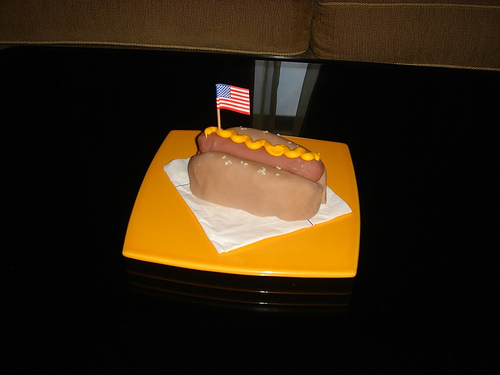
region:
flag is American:
[204, 80, 253, 132]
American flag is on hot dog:
[183, 83, 326, 219]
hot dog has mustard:
[196, 123, 327, 181]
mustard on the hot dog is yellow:
[198, 121, 326, 174]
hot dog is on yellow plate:
[121, 126, 361, 279]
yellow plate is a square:
[123, 127, 358, 279]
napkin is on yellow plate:
[124, 115, 359, 278]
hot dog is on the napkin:
[162, 120, 352, 249]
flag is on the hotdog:
[196, 83, 327, 181]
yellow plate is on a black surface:
[0, 59, 494, 368]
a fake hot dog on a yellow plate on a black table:
[153, 103, 369, 250]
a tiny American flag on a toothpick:
[214, 76, 254, 136]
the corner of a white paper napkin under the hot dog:
[184, 205, 265, 268]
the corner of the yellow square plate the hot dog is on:
[103, 205, 201, 289]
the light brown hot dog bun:
[194, 171, 311, 215]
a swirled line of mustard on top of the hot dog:
[244, 133, 324, 170]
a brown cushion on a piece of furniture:
[314, 6, 497, 71]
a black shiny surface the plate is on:
[85, 278, 368, 363]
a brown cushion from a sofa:
[2, 4, 314, 67]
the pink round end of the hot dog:
[310, 161, 330, 186]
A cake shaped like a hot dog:
[175, 102, 337, 214]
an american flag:
[210, 82, 249, 140]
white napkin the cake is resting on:
[180, 140, 339, 243]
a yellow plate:
[114, 123, 364, 279]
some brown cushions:
[26, 0, 483, 59]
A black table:
[7, 48, 498, 355]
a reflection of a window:
[245, 57, 326, 127]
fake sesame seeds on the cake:
[216, 150, 281, 181]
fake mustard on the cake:
[208, 122, 319, 162]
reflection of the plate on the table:
[146, 273, 356, 308]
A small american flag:
[211, 79, 252, 129]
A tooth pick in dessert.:
[216, 111, 222, 129]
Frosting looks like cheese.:
[209, 123, 321, 165]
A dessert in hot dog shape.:
[186, 111, 326, 227]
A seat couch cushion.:
[323, 2, 498, 67]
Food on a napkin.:
[161, 123, 356, 250]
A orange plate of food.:
[126, 129, 366, 287]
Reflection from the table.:
[116, 274, 361, 315]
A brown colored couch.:
[7, 0, 498, 55]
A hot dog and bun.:
[185, 126, 328, 221]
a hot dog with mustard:
[187, 78, 329, 224]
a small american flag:
[214, 78, 253, 131]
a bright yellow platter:
[117, 127, 364, 282]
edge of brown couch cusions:
[0, 0, 499, 70]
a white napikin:
[163, 157, 352, 253]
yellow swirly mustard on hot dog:
[201, 126, 323, 163]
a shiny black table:
[1, 41, 498, 373]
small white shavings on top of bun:
[221, 123, 295, 180]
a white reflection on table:
[251, 53, 320, 135]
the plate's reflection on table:
[123, 265, 357, 302]